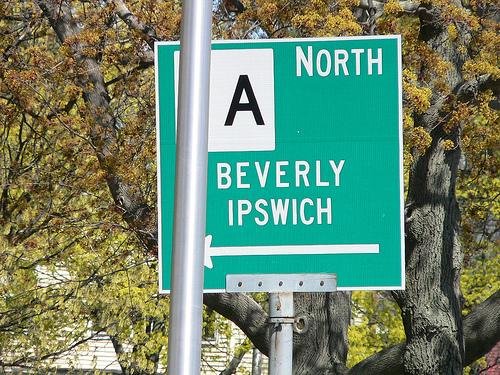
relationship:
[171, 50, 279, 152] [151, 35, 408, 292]
box on sign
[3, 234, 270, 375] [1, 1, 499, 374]
building behind tree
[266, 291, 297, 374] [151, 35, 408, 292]
pole holding sign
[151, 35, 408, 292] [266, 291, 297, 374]
sign on pole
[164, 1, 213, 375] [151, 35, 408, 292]
pole in front of sign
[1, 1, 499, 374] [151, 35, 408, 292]
tree behind sign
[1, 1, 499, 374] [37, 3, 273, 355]
tree has a large branch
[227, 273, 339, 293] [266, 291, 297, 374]
bracket on pole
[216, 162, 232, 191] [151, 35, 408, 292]
letter on sign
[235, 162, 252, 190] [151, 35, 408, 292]
letter on sign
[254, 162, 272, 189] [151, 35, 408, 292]
letter on sign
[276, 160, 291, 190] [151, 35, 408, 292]
letter on sign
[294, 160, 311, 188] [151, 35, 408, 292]
letter on sign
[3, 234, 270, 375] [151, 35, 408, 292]
building behind sign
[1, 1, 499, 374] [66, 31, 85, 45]
tree has a leaf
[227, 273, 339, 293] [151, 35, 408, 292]
bracket on sign